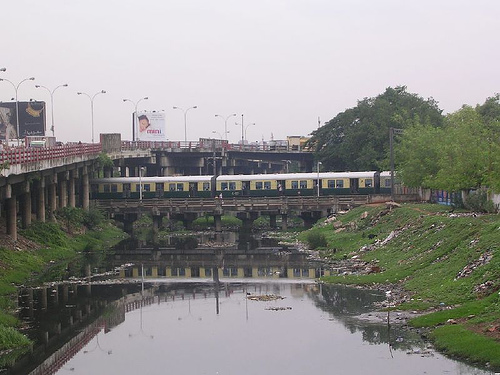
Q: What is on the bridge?
A: Train.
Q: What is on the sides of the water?
A: Grass.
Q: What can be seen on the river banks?
A: Garbage.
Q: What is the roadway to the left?
A: Highway overpass.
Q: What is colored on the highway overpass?
A: Red fence.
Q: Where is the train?
A: On the bridge.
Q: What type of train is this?
A: Passenger train.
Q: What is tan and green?
A: Train.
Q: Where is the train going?
A: Over the bridge.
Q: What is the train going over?
A: Murky water.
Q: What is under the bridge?
A: Pool of water.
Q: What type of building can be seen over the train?
A: Small brown shack.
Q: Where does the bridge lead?
A: Under the road.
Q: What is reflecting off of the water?
A: Train.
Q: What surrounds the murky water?
A: Grass.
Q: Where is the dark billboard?
A: On the left.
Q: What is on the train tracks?
A: A train.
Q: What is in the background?
A: Trees.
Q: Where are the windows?
A: On the train.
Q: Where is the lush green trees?
A: Far right.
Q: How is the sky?
A: Gray.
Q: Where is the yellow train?
A: On tracks.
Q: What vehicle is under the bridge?
A: Train.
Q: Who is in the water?
A: No one.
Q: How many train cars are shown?
A: Three.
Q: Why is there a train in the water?
A: It's a reflection.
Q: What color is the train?
A: White and green.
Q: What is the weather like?
A: Cloudy.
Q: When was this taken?
A: During the day.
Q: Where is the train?
A: Under the bridge.